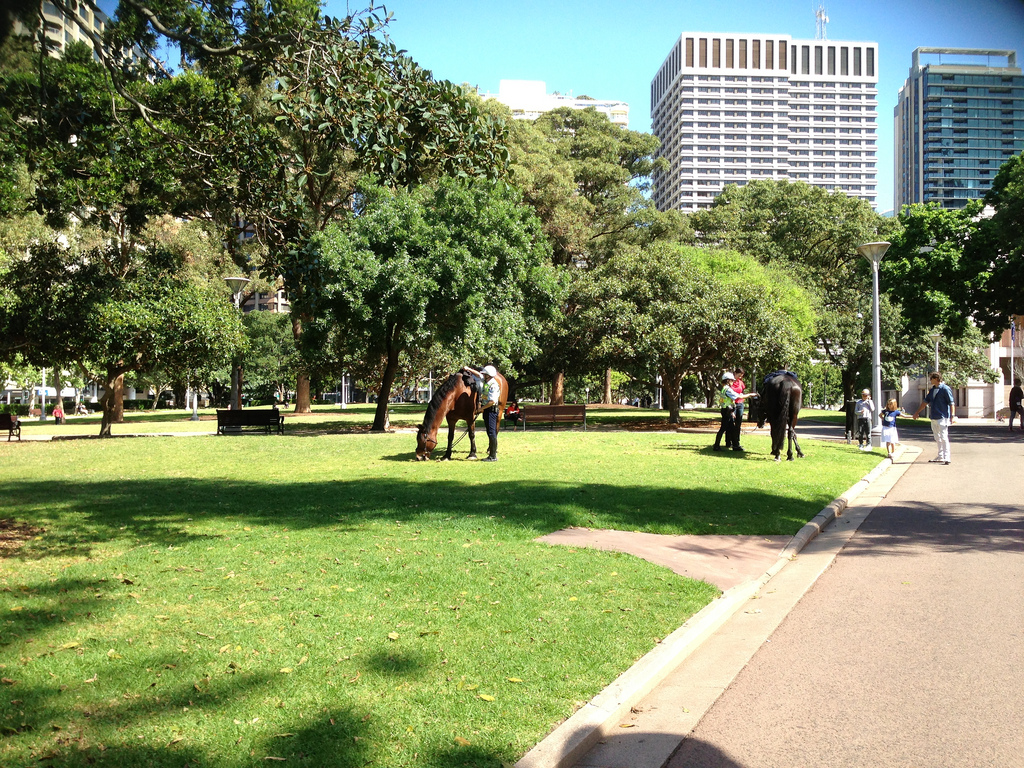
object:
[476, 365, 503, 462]
man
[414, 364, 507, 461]
horse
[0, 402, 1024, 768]
park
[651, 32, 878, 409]
building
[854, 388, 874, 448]
kids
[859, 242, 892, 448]
lightpost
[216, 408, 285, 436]
bench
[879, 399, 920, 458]
child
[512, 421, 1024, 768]
curb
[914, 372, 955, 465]
man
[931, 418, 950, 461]
pants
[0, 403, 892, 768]
grass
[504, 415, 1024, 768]
walkway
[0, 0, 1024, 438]
trees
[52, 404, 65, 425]
people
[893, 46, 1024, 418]
buildings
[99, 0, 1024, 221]
sky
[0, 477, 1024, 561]
shadows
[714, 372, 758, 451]
people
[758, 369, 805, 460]
horse